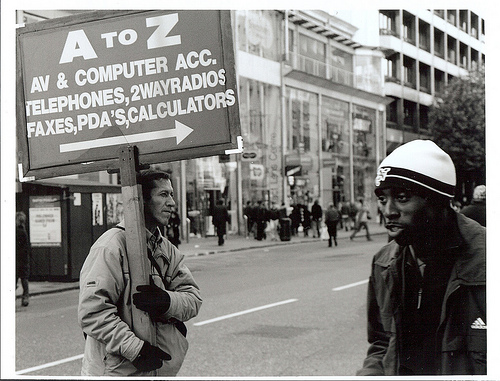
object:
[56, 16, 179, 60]
alphabet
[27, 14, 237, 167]
sign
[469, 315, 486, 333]
logo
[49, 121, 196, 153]
arrow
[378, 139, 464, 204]
hat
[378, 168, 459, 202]
stripes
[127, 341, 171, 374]
gloves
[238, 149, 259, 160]
logo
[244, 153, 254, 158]
mastercard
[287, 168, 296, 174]
subway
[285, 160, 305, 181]
sign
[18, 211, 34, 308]
woman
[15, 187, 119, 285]
busstop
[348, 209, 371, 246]
people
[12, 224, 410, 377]
street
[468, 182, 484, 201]
hair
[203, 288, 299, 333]
line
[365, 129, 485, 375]
man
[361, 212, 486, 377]
jacket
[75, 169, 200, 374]
man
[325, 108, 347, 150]
glass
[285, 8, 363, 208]
building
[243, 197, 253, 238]
people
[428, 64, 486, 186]
tree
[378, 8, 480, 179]
building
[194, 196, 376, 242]
crowd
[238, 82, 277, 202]
store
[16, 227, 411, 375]
road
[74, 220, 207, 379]
jacket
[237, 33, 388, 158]
fronts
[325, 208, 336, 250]
man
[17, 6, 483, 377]
city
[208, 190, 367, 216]
pedestrians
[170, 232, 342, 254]
sidewalk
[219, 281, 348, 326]
lines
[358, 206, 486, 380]
coat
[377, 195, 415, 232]
face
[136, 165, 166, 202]
hair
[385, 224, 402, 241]
mouth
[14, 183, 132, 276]
building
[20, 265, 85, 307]
curb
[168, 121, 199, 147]
right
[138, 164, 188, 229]
head